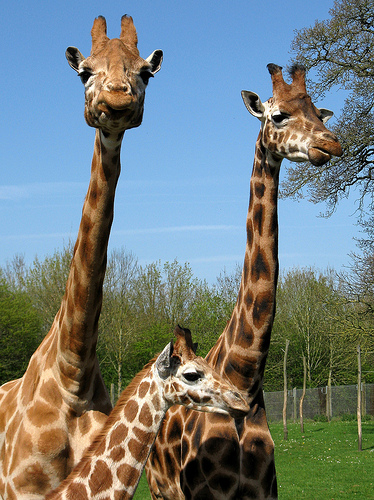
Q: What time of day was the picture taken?
A: Daytime.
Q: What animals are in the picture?
A: Giraffes.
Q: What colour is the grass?
A: Green.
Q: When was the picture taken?
A: Daytime.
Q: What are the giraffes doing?
A: Standing.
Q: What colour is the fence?
A: Grey.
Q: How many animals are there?
A: Three.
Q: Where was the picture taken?
A: In a zoo.